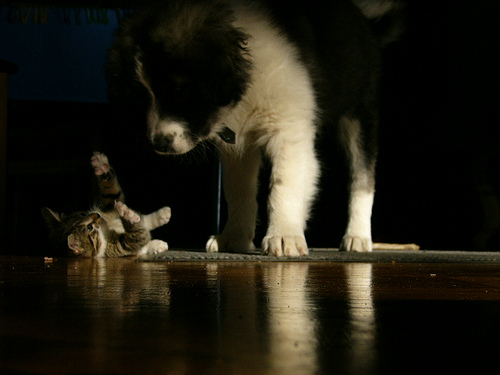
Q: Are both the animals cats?
A: No, they are dogs and cats.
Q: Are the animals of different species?
A: Yes, they are dogs and cats.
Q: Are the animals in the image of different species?
A: Yes, they are dogs and cats.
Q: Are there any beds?
A: No, there are no beds.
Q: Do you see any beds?
A: No, there are no beds.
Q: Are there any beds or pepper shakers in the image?
A: No, there are no beds or pepper shakers.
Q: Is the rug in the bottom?
A: Yes, the rug is in the bottom of the image.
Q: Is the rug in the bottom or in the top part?
A: The rug is in the bottom of the image.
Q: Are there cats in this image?
A: Yes, there is a cat.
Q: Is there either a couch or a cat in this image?
A: Yes, there is a cat.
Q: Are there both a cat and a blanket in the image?
A: No, there is a cat but no blankets.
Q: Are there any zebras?
A: No, there are no zebras.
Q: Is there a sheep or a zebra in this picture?
A: No, there are no zebras or sheep.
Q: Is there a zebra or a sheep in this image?
A: No, there are no zebras or sheep.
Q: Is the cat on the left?
A: Yes, the cat is on the left of the image.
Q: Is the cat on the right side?
A: No, the cat is on the left of the image.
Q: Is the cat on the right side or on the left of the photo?
A: The cat is on the left of the image.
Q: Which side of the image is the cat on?
A: The cat is on the left of the image.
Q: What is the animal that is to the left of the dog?
A: The animal is a cat.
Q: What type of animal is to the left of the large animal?
A: The animal is a cat.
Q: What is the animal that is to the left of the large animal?
A: The animal is a cat.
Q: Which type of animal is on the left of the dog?
A: The animal is a cat.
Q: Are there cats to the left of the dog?
A: Yes, there is a cat to the left of the dog.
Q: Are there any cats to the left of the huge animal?
A: Yes, there is a cat to the left of the dog.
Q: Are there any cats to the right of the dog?
A: No, the cat is to the left of the dog.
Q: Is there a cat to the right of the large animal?
A: No, the cat is to the left of the dog.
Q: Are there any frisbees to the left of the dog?
A: No, there is a cat to the left of the dog.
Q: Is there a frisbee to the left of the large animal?
A: No, there is a cat to the left of the dog.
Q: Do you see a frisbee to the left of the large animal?
A: No, there is a cat to the left of the dog.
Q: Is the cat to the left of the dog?
A: Yes, the cat is to the left of the dog.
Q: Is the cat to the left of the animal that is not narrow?
A: Yes, the cat is to the left of the dog.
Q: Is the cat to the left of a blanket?
A: No, the cat is to the left of the dog.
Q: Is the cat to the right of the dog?
A: No, the cat is to the left of the dog.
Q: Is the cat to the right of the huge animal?
A: No, the cat is to the left of the dog.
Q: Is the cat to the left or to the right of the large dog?
A: The cat is to the left of the dog.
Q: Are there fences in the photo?
A: No, there are no fences.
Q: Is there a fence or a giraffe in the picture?
A: No, there are no fences or giraffes.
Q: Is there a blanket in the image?
A: No, there are no blankets.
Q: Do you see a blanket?
A: No, there are no blankets.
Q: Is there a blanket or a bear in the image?
A: No, there are no blankets or bears.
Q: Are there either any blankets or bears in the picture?
A: No, there are no blankets or bears.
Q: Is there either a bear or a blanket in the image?
A: No, there are no blankets or bears.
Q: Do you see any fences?
A: No, there are no fences.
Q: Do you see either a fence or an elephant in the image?
A: No, there are no fences or elephants.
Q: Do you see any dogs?
A: Yes, there is a dog.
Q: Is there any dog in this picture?
A: Yes, there is a dog.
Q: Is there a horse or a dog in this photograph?
A: Yes, there is a dog.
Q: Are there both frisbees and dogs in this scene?
A: No, there is a dog but no frisbees.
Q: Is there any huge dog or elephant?
A: Yes, there is a huge dog.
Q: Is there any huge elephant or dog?
A: Yes, there is a huge dog.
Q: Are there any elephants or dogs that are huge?
A: Yes, the dog is huge.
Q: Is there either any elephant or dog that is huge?
A: Yes, the dog is huge.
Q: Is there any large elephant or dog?
A: Yes, there is a large dog.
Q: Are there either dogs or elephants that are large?
A: Yes, the dog is large.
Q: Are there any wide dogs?
A: Yes, there is a wide dog.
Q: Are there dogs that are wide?
A: Yes, there is a dog that is wide.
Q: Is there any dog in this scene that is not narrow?
A: Yes, there is a wide dog.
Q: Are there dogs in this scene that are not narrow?
A: Yes, there is a wide dog.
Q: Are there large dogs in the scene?
A: Yes, there is a large dog.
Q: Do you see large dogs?
A: Yes, there is a large dog.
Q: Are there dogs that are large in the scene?
A: Yes, there is a large dog.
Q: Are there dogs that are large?
A: Yes, there is a dog that is large.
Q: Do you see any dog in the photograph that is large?
A: Yes, there is a dog that is large.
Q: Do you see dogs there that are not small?
A: Yes, there is a large dog.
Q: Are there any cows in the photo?
A: No, there are no cows.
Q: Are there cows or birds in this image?
A: No, there are no cows or birds.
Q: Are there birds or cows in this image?
A: No, there are no cows or birds.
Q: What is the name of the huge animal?
A: The animal is a dog.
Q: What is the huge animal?
A: The animal is a dog.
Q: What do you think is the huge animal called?
A: The animal is a dog.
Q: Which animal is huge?
A: The animal is a dog.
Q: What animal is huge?
A: The animal is a dog.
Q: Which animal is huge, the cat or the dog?
A: The dog is huge.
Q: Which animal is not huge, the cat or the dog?
A: The cat is not huge.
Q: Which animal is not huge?
A: The animal is a cat.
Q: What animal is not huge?
A: The animal is a cat.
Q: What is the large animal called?
A: The animal is a dog.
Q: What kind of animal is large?
A: The animal is a dog.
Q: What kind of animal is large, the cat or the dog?
A: The dog is large.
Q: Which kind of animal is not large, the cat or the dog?
A: The cat is not large.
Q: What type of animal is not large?
A: The animal is a cat.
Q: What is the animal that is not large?
A: The animal is a cat.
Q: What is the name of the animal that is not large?
A: The animal is a cat.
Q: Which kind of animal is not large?
A: The animal is a cat.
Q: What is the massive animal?
A: The animal is a dog.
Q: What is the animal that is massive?
A: The animal is a dog.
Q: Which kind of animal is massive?
A: The animal is a dog.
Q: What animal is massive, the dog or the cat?
A: The dog is massive.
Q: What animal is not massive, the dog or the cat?
A: The cat is not massive.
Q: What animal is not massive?
A: The animal is a cat.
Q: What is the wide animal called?
A: The animal is a dog.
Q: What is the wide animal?
A: The animal is a dog.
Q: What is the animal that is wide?
A: The animal is a dog.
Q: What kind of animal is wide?
A: The animal is a dog.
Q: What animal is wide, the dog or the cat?
A: The dog is wide.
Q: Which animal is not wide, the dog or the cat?
A: The cat is not wide.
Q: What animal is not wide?
A: The animal is a cat.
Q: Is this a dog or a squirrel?
A: This is a dog.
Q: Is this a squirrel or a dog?
A: This is a dog.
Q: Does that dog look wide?
A: Yes, the dog is wide.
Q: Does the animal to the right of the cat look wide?
A: Yes, the dog is wide.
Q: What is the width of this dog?
A: The dog is wide.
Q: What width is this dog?
A: The dog is wide.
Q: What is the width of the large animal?
A: The dog is wide.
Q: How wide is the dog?
A: The dog is wide.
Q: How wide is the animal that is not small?
A: The dog is wide.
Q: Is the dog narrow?
A: No, the dog is wide.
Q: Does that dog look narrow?
A: No, the dog is wide.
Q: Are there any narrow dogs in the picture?
A: No, there is a dog but it is wide.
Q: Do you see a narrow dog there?
A: No, there is a dog but it is wide.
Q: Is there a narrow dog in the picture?
A: No, there is a dog but it is wide.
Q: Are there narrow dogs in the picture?
A: No, there is a dog but it is wide.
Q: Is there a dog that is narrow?
A: No, there is a dog but it is wide.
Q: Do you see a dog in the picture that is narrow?
A: No, there is a dog but it is wide.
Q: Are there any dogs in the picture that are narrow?
A: No, there is a dog but it is wide.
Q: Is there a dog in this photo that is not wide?
A: No, there is a dog but it is wide.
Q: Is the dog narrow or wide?
A: The dog is wide.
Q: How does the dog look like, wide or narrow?
A: The dog is wide.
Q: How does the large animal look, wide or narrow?
A: The dog is wide.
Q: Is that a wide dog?
A: Yes, that is a wide dog.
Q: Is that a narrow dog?
A: No, that is a wide dog.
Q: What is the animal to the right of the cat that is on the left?
A: The animal is a dog.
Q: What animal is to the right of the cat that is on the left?
A: The animal is a dog.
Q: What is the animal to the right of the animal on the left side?
A: The animal is a dog.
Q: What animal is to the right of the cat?
A: The animal is a dog.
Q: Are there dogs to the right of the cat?
A: Yes, there is a dog to the right of the cat.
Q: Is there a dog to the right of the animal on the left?
A: Yes, there is a dog to the right of the cat.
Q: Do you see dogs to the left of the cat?
A: No, the dog is to the right of the cat.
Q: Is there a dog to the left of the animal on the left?
A: No, the dog is to the right of the cat.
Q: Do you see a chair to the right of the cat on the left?
A: No, there is a dog to the right of the cat.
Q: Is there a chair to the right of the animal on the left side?
A: No, there is a dog to the right of the cat.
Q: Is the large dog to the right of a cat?
A: Yes, the dog is to the right of a cat.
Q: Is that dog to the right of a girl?
A: No, the dog is to the right of a cat.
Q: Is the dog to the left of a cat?
A: No, the dog is to the right of a cat.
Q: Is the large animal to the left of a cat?
A: No, the dog is to the right of a cat.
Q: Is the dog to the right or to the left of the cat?
A: The dog is to the right of the cat.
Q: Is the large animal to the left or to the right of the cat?
A: The dog is to the right of the cat.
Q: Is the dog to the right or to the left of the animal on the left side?
A: The dog is to the right of the cat.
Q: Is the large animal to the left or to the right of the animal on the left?
A: The dog is to the right of the cat.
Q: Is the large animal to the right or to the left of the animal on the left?
A: The dog is to the right of the cat.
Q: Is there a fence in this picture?
A: No, there are no fences.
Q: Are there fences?
A: No, there are no fences.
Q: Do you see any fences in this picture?
A: No, there are no fences.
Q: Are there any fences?
A: No, there are no fences.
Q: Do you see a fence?
A: No, there are no fences.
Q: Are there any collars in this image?
A: Yes, there is a collar.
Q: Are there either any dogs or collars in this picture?
A: Yes, there is a collar.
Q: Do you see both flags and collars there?
A: No, there is a collar but no flags.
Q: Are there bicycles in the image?
A: No, there are no bicycles.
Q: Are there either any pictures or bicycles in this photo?
A: No, there are no bicycles or pictures.